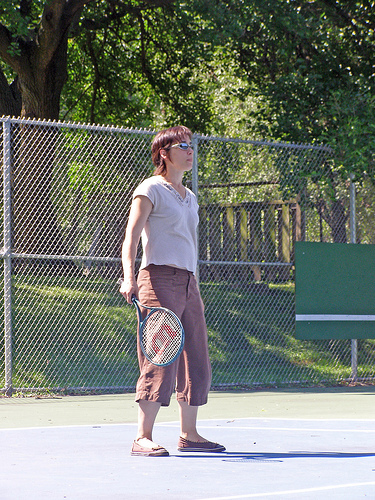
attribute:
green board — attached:
[293, 238, 373, 343]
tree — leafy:
[112, 49, 312, 134]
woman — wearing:
[118, 123, 231, 461]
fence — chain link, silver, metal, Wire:
[0, 114, 373, 392]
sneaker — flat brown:
[176, 432, 227, 452]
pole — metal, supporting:
[347, 341, 364, 382]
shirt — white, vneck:
[131, 175, 203, 275]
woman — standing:
[130, 107, 248, 464]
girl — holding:
[83, 104, 237, 469]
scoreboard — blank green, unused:
[287, 239, 373, 343]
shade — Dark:
[241, 444, 298, 469]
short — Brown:
[193, 368, 205, 387]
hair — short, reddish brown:
[148, 126, 190, 175]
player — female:
[117, 125, 224, 453]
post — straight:
[0, 117, 13, 371]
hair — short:
[145, 124, 190, 143]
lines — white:
[250, 426, 369, 432]